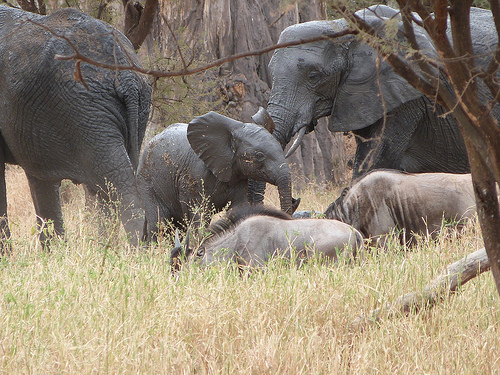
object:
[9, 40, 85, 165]
wrinkled skin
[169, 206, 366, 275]
animal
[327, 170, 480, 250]
animal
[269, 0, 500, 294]
tree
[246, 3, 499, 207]
adult elephant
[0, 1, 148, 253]
adult elephant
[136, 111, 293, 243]
baby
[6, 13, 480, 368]
area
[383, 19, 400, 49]
leaves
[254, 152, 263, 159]
eyelid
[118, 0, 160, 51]
tree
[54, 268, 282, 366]
green grasses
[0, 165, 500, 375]
grass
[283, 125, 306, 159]
tusk